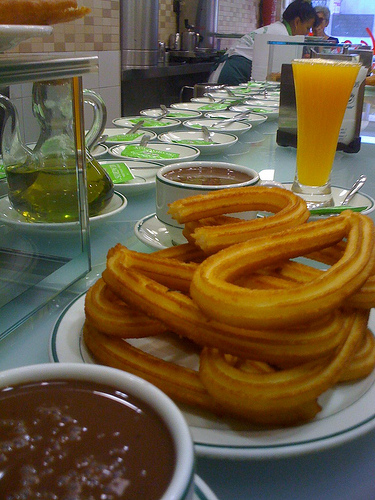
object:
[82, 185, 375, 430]
churros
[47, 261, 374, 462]
plate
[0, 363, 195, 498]
bowl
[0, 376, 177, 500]
sauce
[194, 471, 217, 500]
saucer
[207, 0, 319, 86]
woman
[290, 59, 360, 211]
glass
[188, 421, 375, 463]
trim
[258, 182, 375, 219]
saucer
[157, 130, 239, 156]
plates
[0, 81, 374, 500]
counter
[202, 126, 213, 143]
silverware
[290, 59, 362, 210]
beverage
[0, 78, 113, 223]
pitcher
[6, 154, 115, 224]
oil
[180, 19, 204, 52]
pots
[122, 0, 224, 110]
alcove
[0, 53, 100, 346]
case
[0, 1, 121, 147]
wall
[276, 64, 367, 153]
napkin holder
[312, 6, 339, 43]
lady